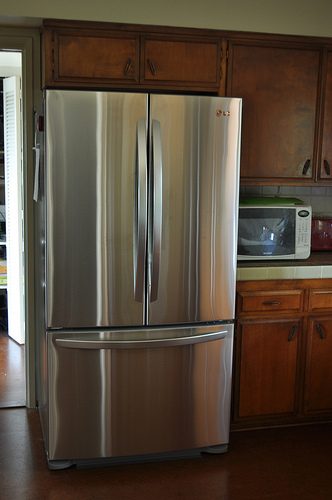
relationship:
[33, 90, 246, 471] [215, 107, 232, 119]
refrigerator has a logo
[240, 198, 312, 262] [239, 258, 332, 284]
microwave on counter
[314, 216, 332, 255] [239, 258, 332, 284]
canister on counter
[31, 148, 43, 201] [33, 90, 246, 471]
paper on fridge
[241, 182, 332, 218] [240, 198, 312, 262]
backsplash behind microwave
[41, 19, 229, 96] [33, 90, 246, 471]
cabinet above fridge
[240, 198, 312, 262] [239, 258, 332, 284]
microwave on countertop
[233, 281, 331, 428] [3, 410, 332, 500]
cabinets are by floor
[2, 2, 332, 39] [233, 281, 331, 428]
wall above cabinets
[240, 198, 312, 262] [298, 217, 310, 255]
microwave has a control panel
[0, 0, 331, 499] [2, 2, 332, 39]
kitchen has a wall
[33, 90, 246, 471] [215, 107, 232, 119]
refrigerator has an emblem